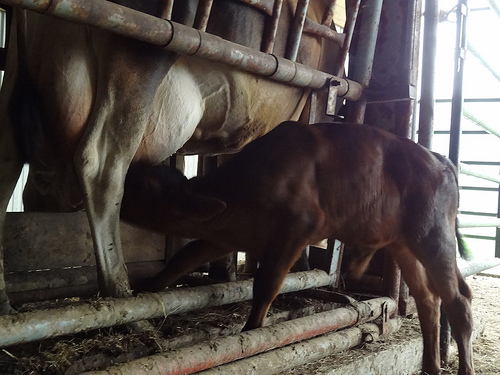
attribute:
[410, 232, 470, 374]
leg — dirty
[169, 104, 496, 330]
baby cow — brown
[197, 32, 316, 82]
brown — metal